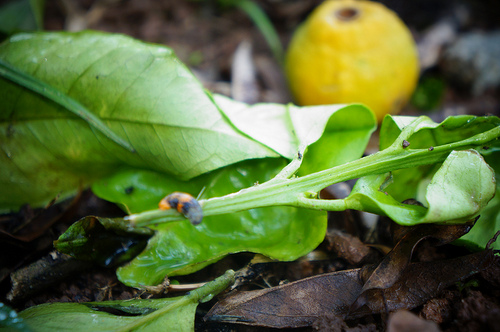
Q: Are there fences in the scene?
A: No, there are no fences.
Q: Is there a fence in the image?
A: No, there are no fences.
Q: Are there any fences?
A: No, there are no fences.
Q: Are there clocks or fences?
A: No, there are no fences or clocks.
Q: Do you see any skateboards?
A: No, there are no skateboards.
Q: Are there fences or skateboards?
A: No, there are no skateboards or fences.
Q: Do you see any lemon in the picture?
A: Yes, there is a lemon.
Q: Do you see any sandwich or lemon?
A: Yes, there is a lemon.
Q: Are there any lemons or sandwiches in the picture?
A: Yes, there is a lemon.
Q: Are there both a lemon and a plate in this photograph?
A: No, there is a lemon but no plates.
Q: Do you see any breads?
A: No, there are no breads.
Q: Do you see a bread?
A: No, there is no breads.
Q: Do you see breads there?
A: No, there are no breads.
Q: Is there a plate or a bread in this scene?
A: No, there are no breads or plates.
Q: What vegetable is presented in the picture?
A: The vegetable is a lemon.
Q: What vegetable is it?
A: The vegetable is a lemon.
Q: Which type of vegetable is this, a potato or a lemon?
A: That is a lemon.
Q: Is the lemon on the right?
A: Yes, the lemon is on the right of the image.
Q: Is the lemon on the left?
A: No, the lemon is on the right of the image.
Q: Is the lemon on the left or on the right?
A: The lemon is on the right of the image.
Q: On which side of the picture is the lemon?
A: The lemon is on the right of the image.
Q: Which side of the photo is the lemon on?
A: The lemon is on the right of the image.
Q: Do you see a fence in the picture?
A: No, there are no fences.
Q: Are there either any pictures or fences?
A: No, there are no fences or pictures.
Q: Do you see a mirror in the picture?
A: No, there are no mirrors.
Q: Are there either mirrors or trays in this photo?
A: No, there are no mirrors or trays.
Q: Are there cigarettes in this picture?
A: No, there are no cigarettes.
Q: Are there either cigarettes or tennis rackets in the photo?
A: No, there are no cigarettes or tennis rackets.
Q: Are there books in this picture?
A: No, there are no books.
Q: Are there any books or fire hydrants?
A: No, there are no books or fire hydrants.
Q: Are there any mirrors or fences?
A: No, there are no fences or mirrors.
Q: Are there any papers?
A: No, there are no papers.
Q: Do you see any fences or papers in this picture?
A: No, there are no papers or fences.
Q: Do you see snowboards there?
A: No, there are no snowboards.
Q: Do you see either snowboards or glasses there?
A: No, there are no snowboards or glasses.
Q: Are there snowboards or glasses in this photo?
A: No, there are no snowboards or glasses.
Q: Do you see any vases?
A: No, there are no vases.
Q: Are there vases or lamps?
A: No, there are no vases or lamps.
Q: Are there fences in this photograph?
A: No, there are no fences.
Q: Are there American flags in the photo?
A: No, there are no American flags.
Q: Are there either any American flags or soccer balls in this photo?
A: No, there are no American flags or soccer balls.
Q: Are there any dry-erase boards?
A: No, there are no dry-erase boards.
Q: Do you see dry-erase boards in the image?
A: No, there are no dry-erase boards.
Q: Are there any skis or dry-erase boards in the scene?
A: No, there are no dry-erase boards or skis.